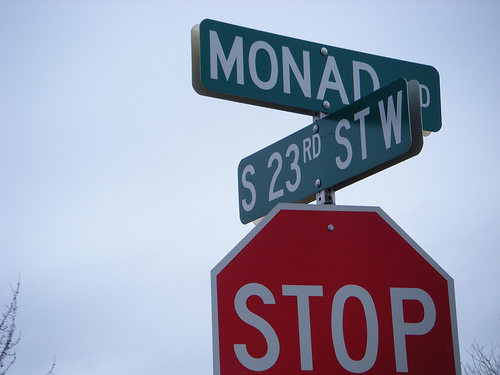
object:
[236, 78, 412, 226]
sign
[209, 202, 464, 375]
stop sign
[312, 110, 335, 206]
pole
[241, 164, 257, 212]
letters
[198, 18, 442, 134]
sign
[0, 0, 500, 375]
sky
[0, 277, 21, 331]
branch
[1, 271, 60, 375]
tree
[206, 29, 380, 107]
text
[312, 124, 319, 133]
bolt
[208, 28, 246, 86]
letter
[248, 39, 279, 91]
letter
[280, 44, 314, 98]
letter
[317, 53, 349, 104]
letter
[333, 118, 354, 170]
letter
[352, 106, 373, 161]
letter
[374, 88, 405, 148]
letter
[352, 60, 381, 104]
letter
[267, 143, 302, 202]
number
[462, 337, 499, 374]
grass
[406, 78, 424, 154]
edge